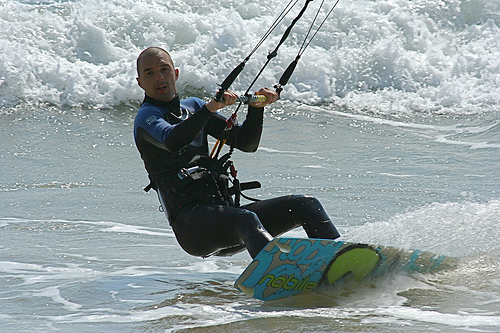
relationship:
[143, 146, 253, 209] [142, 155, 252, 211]
safety on waist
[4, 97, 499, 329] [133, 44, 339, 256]
water near male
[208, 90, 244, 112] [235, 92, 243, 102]
hand gripping handles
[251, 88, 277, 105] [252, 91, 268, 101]
hand gripping handles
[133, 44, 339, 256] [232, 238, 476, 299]
male on board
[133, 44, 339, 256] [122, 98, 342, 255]
male in wetsuit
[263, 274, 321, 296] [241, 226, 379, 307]
writing on board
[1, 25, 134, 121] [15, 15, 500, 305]
wave on sea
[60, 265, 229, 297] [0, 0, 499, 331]
wave on sea